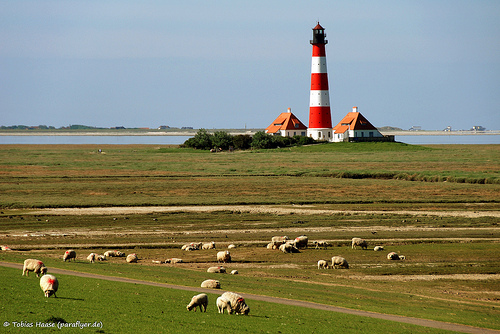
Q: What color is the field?
A: Brown and green.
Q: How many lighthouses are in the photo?
A: 1.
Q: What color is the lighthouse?
A: Red and white.